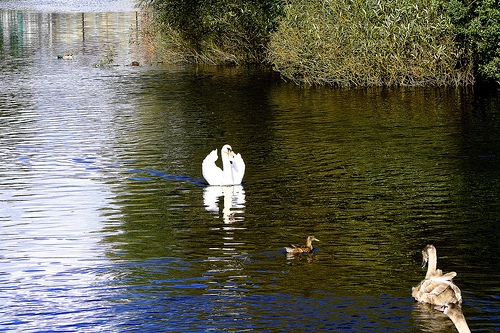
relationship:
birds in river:
[199, 144, 247, 186] [2, 1, 497, 331]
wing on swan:
[203, 144, 221, 184] [199, 145, 246, 188]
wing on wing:
[203, 144, 221, 184] [228, 151, 245, 190]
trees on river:
[272, 18, 490, 105] [322, 81, 461, 223]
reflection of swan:
[199, 184, 254, 224] [195, 140, 249, 185]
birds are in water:
[197, 140, 245, 186] [95, 88, 492, 326]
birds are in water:
[282, 229, 323, 255] [95, 88, 492, 326]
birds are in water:
[411, 238, 473, 325] [95, 88, 492, 326]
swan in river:
[197, 136, 251, 187] [2, 1, 497, 331]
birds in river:
[282, 234, 320, 253] [2, 1, 497, 331]